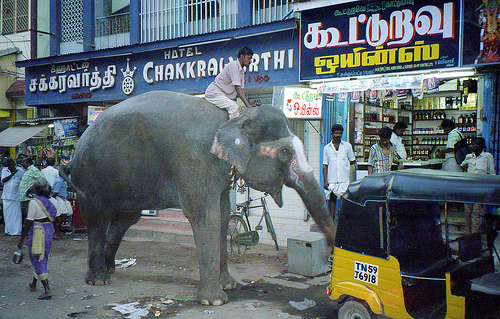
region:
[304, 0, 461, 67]
sign for the store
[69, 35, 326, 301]
man on the elephant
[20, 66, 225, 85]
logo on the wall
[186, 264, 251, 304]
feet on the elephant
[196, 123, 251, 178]
ear on the elephant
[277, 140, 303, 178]
eye of the elephant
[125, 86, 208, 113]
back of the elephant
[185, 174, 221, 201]
the elephant is rgey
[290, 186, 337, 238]
trunk of the elephant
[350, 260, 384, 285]
sign on the vehicle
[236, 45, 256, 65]
Man has dark hair.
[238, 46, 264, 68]
Man has short hair.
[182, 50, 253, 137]
Person sitting on top of elephant.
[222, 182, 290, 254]
Green bike on side of road.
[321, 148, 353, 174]
Man wearing white shirt.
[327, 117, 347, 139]
Man has dark hair.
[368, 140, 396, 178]
Man wearing striped shirt.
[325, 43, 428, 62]
Yellow writing on store sign.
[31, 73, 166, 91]
White writing on store front.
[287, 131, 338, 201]
White markings on elephant's face.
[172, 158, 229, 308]
front leg of an elephant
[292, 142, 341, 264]
trunk of an elephant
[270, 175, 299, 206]
mouth of an elephant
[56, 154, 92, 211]
tail of an elephant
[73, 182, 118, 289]
rear leg of an elephant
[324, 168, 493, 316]
black and yellow carriage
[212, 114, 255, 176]
ear of an elephant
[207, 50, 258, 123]
person on top of an elephant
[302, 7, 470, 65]
white and yellow lettering on blue sign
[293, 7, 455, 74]
white with red out line lettering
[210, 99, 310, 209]
head of an elephant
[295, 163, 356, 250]
nose of an elephant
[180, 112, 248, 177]
ear of an elephant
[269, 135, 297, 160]
eye of an elephant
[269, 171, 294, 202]
mouth of an elephant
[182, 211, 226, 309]
leg of an elephant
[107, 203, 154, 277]
leg of an elephant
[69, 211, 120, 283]
leg of an elephant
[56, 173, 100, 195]
tail of an elephant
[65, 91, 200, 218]
body of an elephant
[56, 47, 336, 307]
a man riding an elephant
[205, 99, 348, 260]
the head of an elephant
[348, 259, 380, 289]
a licence plate on a car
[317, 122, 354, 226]
a man standing on the street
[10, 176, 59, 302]
a woman wearing a purple dress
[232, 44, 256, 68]
the head of a man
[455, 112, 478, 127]
three bottles of alcohol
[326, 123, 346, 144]
the head of a man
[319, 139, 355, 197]
a white button down shirt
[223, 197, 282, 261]
a green bicycle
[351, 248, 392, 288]
jeep has sign on it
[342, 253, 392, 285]
sign is white in color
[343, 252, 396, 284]
sign has black letters on it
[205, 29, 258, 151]
man on the elephant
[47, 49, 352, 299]
elepahant on the road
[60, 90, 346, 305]
a large grey elephant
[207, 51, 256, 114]
a person is sitting down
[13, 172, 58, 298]
a person walking on a street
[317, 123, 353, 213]
a person is standing up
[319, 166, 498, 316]
a car on a street